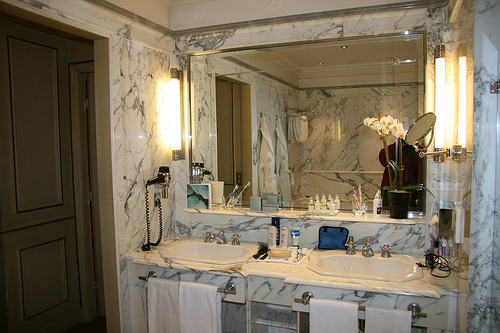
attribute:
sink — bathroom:
[157, 240, 262, 267]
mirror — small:
[190, 57, 435, 226]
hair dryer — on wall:
[135, 164, 172, 251]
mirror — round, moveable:
[403, 112, 435, 144]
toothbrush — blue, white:
[220, 178, 254, 205]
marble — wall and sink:
[267, 257, 377, 307]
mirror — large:
[183, 28, 431, 225]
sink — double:
[141, 228, 481, 326]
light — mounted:
[157, 64, 188, 156]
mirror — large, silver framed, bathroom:
[179, 42, 453, 227]